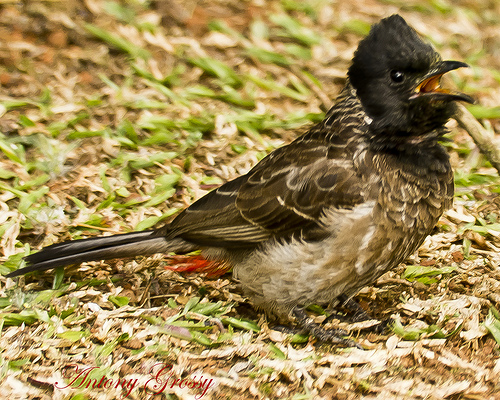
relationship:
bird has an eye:
[5, 13, 476, 348] [388, 68, 407, 82]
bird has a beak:
[5, 13, 476, 348] [409, 60, 477, 106]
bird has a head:
[5, 13, 476, 348] [349, 13, 475, 139]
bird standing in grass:
[5, 13, 476, 348] [1, 2, 499, 398]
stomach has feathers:
[297, 205, 400, 317] [279, 245, 365, 297]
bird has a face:
[5, 13, 476, 348] [382, 41, 473, 122]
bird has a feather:
[5, 13, 476, 348] [3, 234, 200, 279]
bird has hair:
[5, 13, 476, 348] [348, 12, 438, 73]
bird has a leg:
[5, 13, 476, 348] [283, 299, 324, 336]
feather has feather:
[3, 234, 200, 279] [3, 234, 200, 279]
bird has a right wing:
[5, 13, 476, 348] [164, 142, 363, 252]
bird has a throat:
[5, 13, 476, 348] [370, 120, 450, 158]